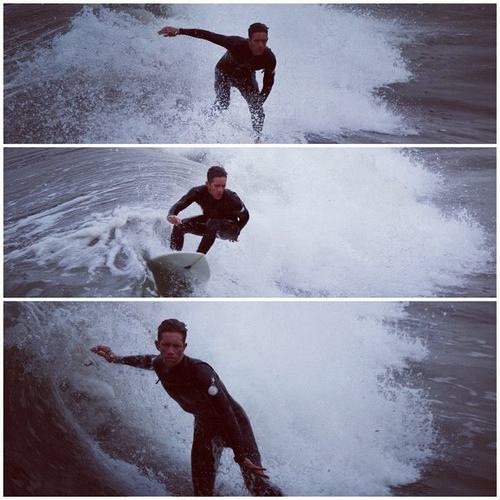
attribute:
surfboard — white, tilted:
[141, 248, 219, 293]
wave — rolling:
[89, 152, 495, 289]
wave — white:
[3, 301, 442, 495]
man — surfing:
[164, 161, 252, 258]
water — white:
[416, 43, 455, 94]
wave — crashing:
[364, 167, 446, 259]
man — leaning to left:
[161, 161, 264, 246]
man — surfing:
[117, 144, 314, 268]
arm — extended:
[92, 333, 157, 370]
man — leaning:
[150, 17, 298, 137]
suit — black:
[124, 354, 273, 499]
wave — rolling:
[6, 146, 491, 295]